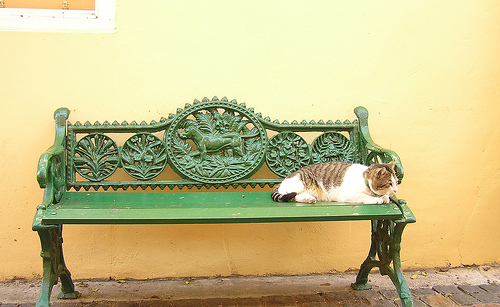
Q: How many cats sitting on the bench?
A: One.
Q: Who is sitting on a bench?
A: A cat.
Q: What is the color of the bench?
A: Green.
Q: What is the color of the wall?
A: Yellow.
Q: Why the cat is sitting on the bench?
A: Resting.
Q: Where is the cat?
A: On the bench.